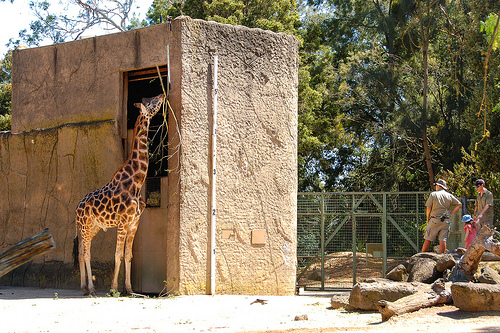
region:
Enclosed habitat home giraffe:
[65, 93, 437, 326]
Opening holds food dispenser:
[112, 70, 187, 236]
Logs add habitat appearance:
[339, 256, 486, 326]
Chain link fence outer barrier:
[299, 184, 406, 294]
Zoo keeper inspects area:
[419, 172, 461, 249]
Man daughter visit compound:
[459, 174, 499, 245]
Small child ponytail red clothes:
[456, 211, 478, 258]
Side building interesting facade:
[224, 30, 292, 285]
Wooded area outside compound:
[323, 4, 437, 181]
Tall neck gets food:
[132, 75, 177, 170]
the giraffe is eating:
[69, 92, 171, 292]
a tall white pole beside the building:
[202, 50, 227, 295]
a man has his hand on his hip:
[418, 175, 463, 253]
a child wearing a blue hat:
[460, 210, 480, 252]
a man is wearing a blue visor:
[470, 177, 497, 231]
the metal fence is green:
[290, 186, 492, 291]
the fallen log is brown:
[373, 229, 489, 327]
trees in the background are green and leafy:
[152, 1, 495, 256]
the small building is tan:
[8, 14, 305, 301]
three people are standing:
[415, 170, 496, 261]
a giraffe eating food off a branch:
[75, 97, 160, 301]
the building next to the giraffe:
[0, 17, 295, 292]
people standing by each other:
[416, 177, 492, 255]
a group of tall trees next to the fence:
[171, 0, 491, 192]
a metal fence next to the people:
[297, 190, 499, 280]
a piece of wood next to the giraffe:
[1, 227, 55, 277]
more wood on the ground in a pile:
[348, 250, 497, 322]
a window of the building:
[121, 73, 170, 173]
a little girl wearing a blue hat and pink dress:
[458, 210, 480, 244]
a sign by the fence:
[365, 240, 387, 260]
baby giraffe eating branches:
[14, 31, 236, 299]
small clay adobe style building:
[10, 28, 307, 293]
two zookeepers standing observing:
[415, 175, 495, 249]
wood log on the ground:
[346, 268, 478, 323]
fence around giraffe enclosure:
[299, 185, 499, 300]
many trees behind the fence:
[296, 65, 498, 185]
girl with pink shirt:
[456, 211, 481, 248]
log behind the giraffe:
[1, 223, 68, 291]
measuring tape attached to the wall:
[208, 44, 226, 294]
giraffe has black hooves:
[79, 285, 141, 302]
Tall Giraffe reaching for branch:
[63, 81, 170, 295]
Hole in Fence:
[352, 195, 367, 212]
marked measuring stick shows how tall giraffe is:
[204, 44, 221, 293]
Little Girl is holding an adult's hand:
[458, 174, 496, 255]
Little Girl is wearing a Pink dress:
[457, 211, 481, 255]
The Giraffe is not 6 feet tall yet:
[68, 46, 220, 295]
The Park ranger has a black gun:
[418, 173, 462, 257]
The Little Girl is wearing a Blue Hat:
[460, 211, 473, 226]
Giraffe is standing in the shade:
[5, 55, 307, 292]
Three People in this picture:
[416, 172, 497, 262]